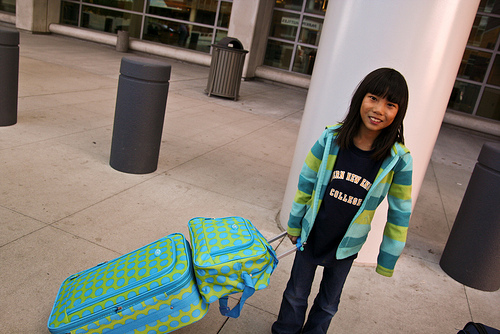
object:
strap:
[217, 274, 256, 320]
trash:
[203, 37, 250, 101]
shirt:
[306, 138, 392, 262]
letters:
[328, 170, 372, 207]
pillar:
[274, 0, 481, 264]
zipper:
[51, 273, 193, 334]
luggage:
[43, 215, 309, 334]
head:
[359, 67, 408, 133]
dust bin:
[204, 37, 251, 101]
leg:
[302, 267, 348, 334]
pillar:
[105, 54, 171, 177]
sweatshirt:
[286, 117, 413, 278]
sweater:
[286, 124, 412, 278]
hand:
[286, 234, 297, 244]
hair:
[329, 67, 406, 160]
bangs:
[361, 69, 405, 105]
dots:
[46, 216, 279, 334]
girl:
[268, 65, 414, 334]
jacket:
[285, 121, 414, 277]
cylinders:
[109, 54, 172, 174]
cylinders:
[438, 142, 500, 293]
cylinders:
[0, 29, 20, 127]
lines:
[206, 48, 246, 102]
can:
[203, 36, 249, 101]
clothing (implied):
[285, 124, 413, 278]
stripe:
[386, 209, 411, 227]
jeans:
[269, 245, 359, 334]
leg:
[267, 263, 313, 333]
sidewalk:
[0, 19, 500, 332]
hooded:
[399, 150, 411, 159]